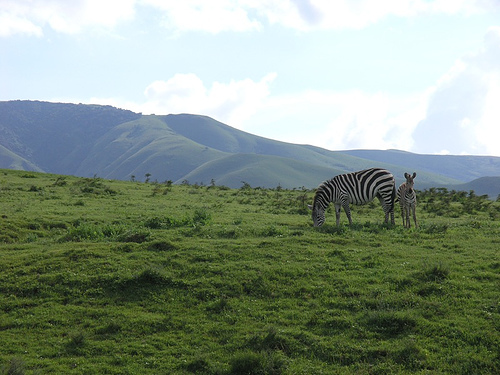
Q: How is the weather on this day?
A: It is overcast.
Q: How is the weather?
A: It is overcast.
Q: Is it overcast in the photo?
A: Yes, it is overcast.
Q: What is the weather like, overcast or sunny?
A: It is overcast.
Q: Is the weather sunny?
A: No, it is overcast.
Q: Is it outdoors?
A: Yes, it is outdoors.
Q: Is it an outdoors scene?
A: Yes, it is outdoors.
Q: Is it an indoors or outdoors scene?
A: It is outdoors.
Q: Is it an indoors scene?
A: No, it is outdoors.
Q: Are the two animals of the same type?
A: Yes, all the animals are zebras.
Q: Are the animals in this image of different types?
A: No, all the animals are zebras.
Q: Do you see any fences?
A: No, there are no fences.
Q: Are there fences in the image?
A: No, there are no fences.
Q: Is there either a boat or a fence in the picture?
A: No, there are no fences or boats.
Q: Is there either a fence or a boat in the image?
A: No, there are no fences or boats.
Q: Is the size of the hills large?
A: Yes, the hills are large.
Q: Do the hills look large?
A: Yes, the hills are large.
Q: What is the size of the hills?
A: The hills are large.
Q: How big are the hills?
A: The hills are large.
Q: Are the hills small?
A: No, the hills are large.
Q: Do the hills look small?
A: No, the hills are large.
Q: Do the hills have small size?
A: No, the hills are large.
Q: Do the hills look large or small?
A: The hills are large.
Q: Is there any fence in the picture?
A: No, there are no fences.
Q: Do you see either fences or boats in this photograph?
A: No, there are no fences or boats.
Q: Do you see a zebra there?
A: Yes, there is a zebra.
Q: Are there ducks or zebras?
A: Yes, there is a zebra.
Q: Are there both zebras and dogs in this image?
A: No, there is a zebra but no dogs.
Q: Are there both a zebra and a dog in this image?
A: No, there is a zebra but no dogs.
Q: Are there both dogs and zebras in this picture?
A: No, there is a zebra but no dogs.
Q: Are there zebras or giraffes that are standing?
A: Yes, the zebra is standing.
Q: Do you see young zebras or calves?
A: Yes, there is a young zebra.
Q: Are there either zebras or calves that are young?
A: Yes, the zebra is young.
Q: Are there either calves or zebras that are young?
A: Yes, the zebra is young.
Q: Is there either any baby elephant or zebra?
A: Yes, there is a baby zebra.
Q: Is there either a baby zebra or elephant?
A: Yes, there is a baby zebra.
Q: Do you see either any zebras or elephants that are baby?
A: Yes, the zebra is a baby.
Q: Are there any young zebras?
A: Yes, there is a young zebra.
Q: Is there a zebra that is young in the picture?
A: Yes, there is a young zebra.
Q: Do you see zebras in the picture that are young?
A: Yes, there is a zebra that is young.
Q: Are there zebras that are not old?
A: Yes, there is an young zebra.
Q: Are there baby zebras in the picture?
A: Yes, there is a baby zebra.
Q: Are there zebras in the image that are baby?
A: Yes, there is a zebra that is a baby.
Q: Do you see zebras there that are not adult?
A: Yes, there is an baby zebra.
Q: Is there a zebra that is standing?
A: Yes, there is a zebra that is standing.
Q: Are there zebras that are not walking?
A: Yes, there is a zebra that is standing.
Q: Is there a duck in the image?
A: No, there are no ducks.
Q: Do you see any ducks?
A: No, there are no ducks.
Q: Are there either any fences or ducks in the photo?
A: No, there are no ducks or fences.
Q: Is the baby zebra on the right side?
A: Yes, the zebra is on the right of the image.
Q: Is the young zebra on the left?
A: No, the zebra is on the right of the image.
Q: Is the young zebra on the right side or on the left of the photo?
A: The zebra is on the right of the image.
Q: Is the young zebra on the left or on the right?
A: The zebra is on the right of the image.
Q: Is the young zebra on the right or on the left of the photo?
A: The zebra is on the right of the image.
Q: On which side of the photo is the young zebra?
A: The zebra is on the right of the image.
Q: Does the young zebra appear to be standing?
A: Yes, the zebra is standing.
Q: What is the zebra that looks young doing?
A: The zebra is standing.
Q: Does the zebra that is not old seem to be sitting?
A: No, the zebra is standing.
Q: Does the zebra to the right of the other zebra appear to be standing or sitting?
A: The zebra is standing.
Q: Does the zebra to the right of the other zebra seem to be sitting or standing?
A: The zebra is standing.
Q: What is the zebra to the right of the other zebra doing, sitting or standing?
A: The zebra is standing.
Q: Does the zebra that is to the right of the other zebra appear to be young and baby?
A: Yes, the zebra is young and baby.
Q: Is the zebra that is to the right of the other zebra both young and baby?
A: Yes, the zebra is young and baby.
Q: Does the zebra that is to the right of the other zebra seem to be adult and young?
A: No, the zebra is young but baby.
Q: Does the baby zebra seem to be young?
A: Yes, the zebra is young.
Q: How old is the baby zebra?
A: The zebra is young.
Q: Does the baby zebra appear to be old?
A: No, the zebra is young.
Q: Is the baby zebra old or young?
A: The zebra is young.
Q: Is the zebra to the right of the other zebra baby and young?
A: Yes, the zebra is a baby and young.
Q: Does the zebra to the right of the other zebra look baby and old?
A: No, the zebra is a baby but young.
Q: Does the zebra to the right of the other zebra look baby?
A: Yes, the zebra is a baby.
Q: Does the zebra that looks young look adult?
A: No, the zebra is a baby.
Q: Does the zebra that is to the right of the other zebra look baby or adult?
A: The zebra is a baby.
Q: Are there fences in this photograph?
A: No, there are no fences.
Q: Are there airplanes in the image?
A: No, there are no airplanes.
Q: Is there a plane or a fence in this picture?
A: No, there are no airplanes or fences.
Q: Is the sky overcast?
A: Yes, the sky is overcast.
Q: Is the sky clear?
A: No, the sky is overcast.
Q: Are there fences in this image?
A: No, there are no fences.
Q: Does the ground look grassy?
A: Yes, the ground is grassy.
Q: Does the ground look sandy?
A: No, the ground is grassy.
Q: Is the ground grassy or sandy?
A: The ground is grassy.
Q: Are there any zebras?
A: Yes, there is a zebra.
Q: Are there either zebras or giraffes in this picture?
A: Yes, there is a zebra.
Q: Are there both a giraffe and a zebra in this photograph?
A: No, there is a zebra but no giraffes.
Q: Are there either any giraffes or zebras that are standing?
A: Yes, the zebra is standing.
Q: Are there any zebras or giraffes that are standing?
A: Yes, the zebra is standing.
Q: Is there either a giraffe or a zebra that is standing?
A: Yes, the zebra is standing.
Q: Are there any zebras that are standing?
A: Yes, there is a zebra that is standing.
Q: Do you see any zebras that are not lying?
A: Yes, there is a zebra that is standing .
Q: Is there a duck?
A: No, there are no ducks.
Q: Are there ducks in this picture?
A: No, there are no ducks.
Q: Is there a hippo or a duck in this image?
A: No, there are no ducks or hippos.